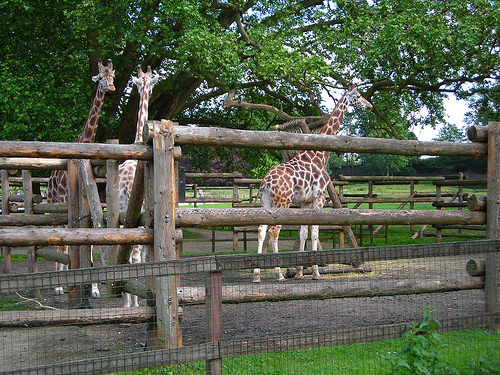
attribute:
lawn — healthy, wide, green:
[185, 323, 494, 368]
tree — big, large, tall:
[4, 1, 500, 159]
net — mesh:
[1, 238, 500, 374]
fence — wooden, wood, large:
[1, 122, 497, 363]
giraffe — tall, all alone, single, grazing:
[258, 86, 371, 277]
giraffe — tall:
[112, 64, 166, 213]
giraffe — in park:
[57, 56, 115, 205]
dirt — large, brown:
[23, 257, 481, 347]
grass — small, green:
[171, 332, 496, 366]